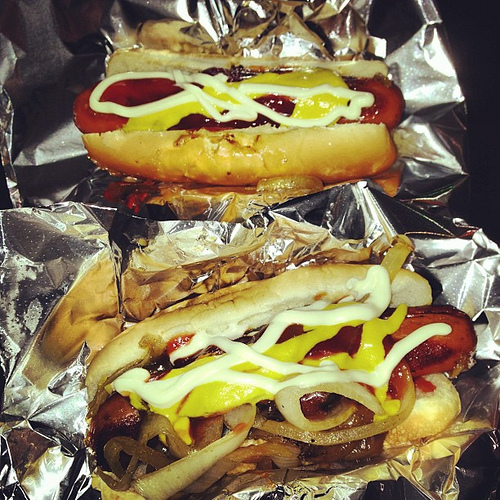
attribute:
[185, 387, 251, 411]
mustard — yellow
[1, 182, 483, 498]
foil — aluminum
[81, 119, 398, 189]
bun — golden brown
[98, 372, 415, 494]
onions — cooked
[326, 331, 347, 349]
ketchup — red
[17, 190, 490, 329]
foil — aluminum, heat insulator